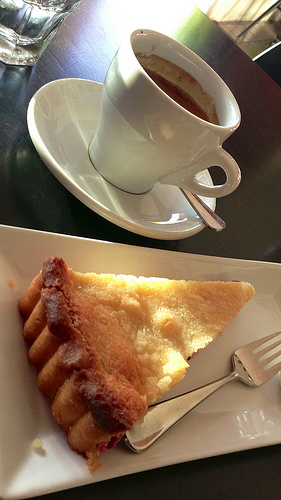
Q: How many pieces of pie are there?
A: One.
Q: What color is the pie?
A: Beige.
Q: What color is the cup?
A: White.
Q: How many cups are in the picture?
A: Just one.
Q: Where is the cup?
A: On the plate.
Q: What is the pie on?
A: A plate on the table.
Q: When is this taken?
A: During a snack or meal.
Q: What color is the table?
A: Brown.